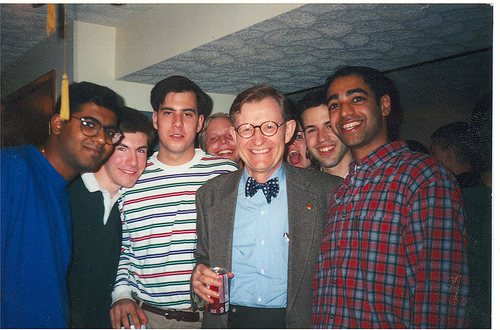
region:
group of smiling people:
[1, 66, 474, 327]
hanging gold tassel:
[60, 4, 70, 120]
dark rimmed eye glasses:
[67, 112, 124, 146]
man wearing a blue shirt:
[1, 77, 128, 325]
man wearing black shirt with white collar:
[65, 106, 151, 326]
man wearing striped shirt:
[110, 75, 239, 329]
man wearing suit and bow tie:
[188, 85, 346, 327]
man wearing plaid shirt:
[309, 64, 474, 329]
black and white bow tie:
[243, 175, 283, 201]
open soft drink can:
[203, 266, 230, 315]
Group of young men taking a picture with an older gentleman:
[3, 67, 479, 324]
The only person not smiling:
[151, 78, 206, 157]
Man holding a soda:
[183, 92, 333, 328]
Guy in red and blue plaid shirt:
[312, 64, 478, 326]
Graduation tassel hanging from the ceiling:
[43, 0, 85, 132]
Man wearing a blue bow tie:
[185, 88, 340, 328]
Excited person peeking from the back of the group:
[276, 107, 319, 172]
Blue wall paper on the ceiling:
[113, 0, 498, 100]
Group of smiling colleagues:
[4, 77, 454, 316]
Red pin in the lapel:
[296, 192, 325, 222]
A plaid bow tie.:
[238, 177, 283, 201]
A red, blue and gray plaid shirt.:
[330, 149, 467, 326]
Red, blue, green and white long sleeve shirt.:
[117, 157, 219, 309]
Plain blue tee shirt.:
[8, 142, 82, 328]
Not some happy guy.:
[148, 75, 208, 156]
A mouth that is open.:
[284, 147, 304, 165]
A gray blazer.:
[195, 168, 330, 328]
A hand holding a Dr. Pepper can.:
[203, 263, 236, 316]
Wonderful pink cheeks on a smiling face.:
[106, 125, 154, 187]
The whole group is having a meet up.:
[16, 72, 474, 197]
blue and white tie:
[236, 166, 290, 201]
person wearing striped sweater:
[112, 143, 235, 325]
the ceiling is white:
[130, 37, 370, 76]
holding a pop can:
[181, 248, 258, 308]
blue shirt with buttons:
[230, 157, 292, 310]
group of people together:
[8, 40, 477, 260]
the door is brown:
[3, 69, 77, 148]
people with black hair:
[52, 53, 230, 159]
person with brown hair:
[232, 76, 303, 161]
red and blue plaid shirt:
[316, 136, 443, 326]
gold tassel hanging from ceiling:
[34, 1, 81, 121]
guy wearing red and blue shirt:
[307, 62, 487, 329]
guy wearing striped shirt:
[131, 73, 221, 327]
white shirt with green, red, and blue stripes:
[130, 161, 212, 322]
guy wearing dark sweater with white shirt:
[52, 108, 148, 325]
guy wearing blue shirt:
[8, 81, 106, 323]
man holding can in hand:
[181, 81, 347, 326]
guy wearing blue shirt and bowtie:
[198, 78, 334, 258]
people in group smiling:
[193, 71, 422, 216]